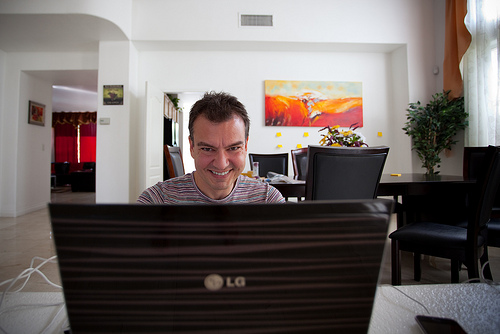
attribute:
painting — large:
[265, 80, 362, 128]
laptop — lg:
[52, 200, 385, 331]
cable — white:
[377, 276, 434, 313]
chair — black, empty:
[299, 134, 393, 205]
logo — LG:
[198, 274, 245, 291]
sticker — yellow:
[373, 125, 391, 155]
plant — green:
[403, 87, 470, 179]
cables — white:
[0, 247, 52, 301]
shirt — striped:
[136, 168, 288, 202]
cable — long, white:
[0, 250, 60, 302]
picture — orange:
[259, 75, 366, 128]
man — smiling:
[187, 87, 246, 184]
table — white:
[371, 276, 498, 329]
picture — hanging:
[28, 100, 45, 124]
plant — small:
[391, 75, 473, 188]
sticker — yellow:
[273, 129, 282, 137]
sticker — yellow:
[274, 144, 281, 149]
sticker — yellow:
[274, 130, 280, 137]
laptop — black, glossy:
[33, 176, 430, 332]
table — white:
[0, 281, 498, 331]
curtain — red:
[80, 115, 95, 161]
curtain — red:
[52, 121, 76, 164]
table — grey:
[21, 186, 471, 332]